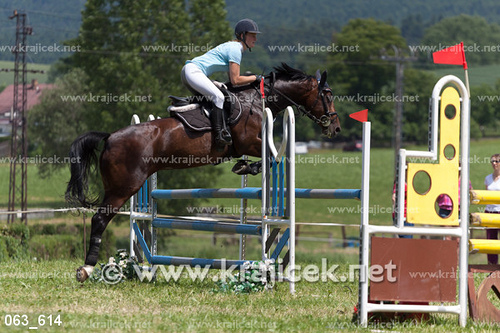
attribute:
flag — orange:
[432, 38, 482, 73]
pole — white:
[344, 108, 379, 330]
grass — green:
[4, 133, 496, 331]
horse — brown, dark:
[65, 60, 342, 284]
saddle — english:
[166, 83, 242, 132]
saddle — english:
[163, 90, 254, 134]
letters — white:
[139, 263, 401, 284]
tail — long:
[58, 129, 106, 209]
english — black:
[166, 86, 256, 168]